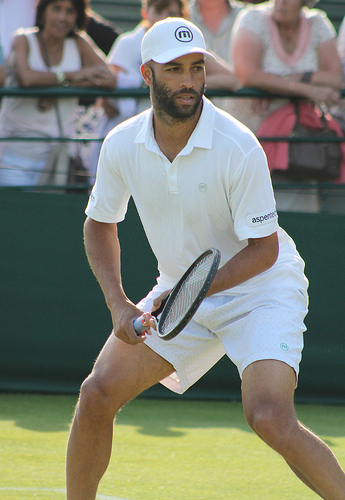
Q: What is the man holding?
A: A racket.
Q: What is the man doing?
A: Playing tennis.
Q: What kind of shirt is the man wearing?
A: A white shirt.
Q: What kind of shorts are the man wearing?
A: White shorts.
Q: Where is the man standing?
A: On the ground.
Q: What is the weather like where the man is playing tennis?
A: It is sunny.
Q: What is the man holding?
A: A tennis racquet.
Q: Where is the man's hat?
A: On his head.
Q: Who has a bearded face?
A: The man playing tennis.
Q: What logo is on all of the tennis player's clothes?
A: Circle with the letter m.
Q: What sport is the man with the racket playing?
A: Tennis.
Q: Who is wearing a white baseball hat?
A: Man playing tennis.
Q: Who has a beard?
A: Tennis player.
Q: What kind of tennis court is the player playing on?
A: Grass.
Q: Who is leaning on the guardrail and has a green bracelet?
A: Woman on the left.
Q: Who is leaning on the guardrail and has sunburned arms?
A: Woman on the right.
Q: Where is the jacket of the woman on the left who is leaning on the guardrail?
A: Tied around her waist.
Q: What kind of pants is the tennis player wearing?
A: White shorts.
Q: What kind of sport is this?
A: TENNIS.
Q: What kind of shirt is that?
A: A white shirt.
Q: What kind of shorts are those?
A: White shorts with a green logo.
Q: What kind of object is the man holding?
A: A tennis racquet.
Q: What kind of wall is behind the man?
A: A green wall.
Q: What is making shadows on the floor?
A: The bystanders.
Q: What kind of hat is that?
A: A hat with an M logo.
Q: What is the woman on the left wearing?
A: A wristband.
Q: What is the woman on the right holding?
A: A brown bag.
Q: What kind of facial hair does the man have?
A: A dark beard.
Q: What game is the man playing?
A: Tennis.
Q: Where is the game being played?
A: Tennis court.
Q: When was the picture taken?
A: Daytime.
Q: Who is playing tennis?
A: A man.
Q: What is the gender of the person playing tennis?
A: Male.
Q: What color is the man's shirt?
A: White.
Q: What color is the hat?
A: White.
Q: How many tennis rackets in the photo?
A: One.